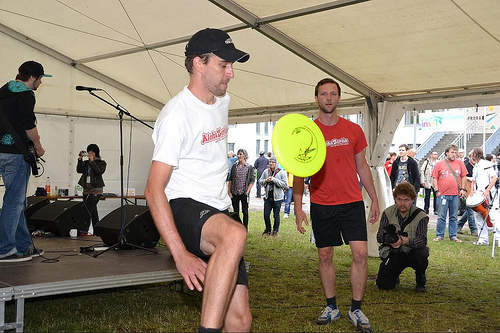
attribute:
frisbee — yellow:
[268, 111, 341, 173]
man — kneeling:
[295, 70, 378, 326]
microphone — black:
[65, 73, 141, 156]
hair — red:
[304, 70, 341, 96]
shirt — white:
[141, 77, 252, 219]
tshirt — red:
[287, 113, 380, 221]